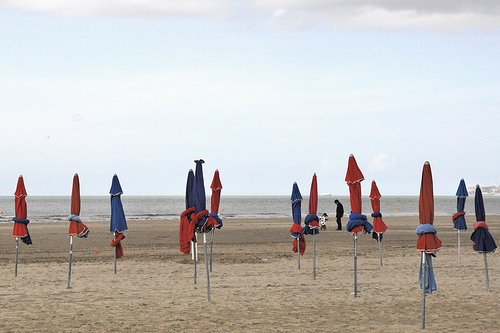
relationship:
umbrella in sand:
[11, 173, 33, 277] [3, 282, 55, 318]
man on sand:
[332, 198, 344, 232] [8, 216, 498, 331]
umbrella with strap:
[11, 172, 31, 278] [11, 215, 29, 222]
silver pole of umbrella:
[67, 232, 73, 289] [68, 172, 90, 238]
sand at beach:
[249, 296, 294, 321] [3, 217, 498, 332]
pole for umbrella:
[482, 254, 490, 290] [468, 185, 495, 290]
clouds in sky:
[1, 8, 499, 189] [6, 8, 498, 197]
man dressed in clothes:
[332, 198, 344, 232] [332, 205, 346, 226]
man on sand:
[332, 198, 344, 232] [0, 215, 499, 332]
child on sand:
[318, 211, 329, 232] [0, 215, 499, 332]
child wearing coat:
[318, 210, 328, 231] [319, 216, 327, 226]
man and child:
[332, 198, 347, 233] [318, 211, 329, 232]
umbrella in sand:
[11, 173, 33, 277] [8, 216, 498, 331]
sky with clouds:
[6, 8, 498, 197] [69, 54, 424, 126]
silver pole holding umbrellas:
[67, 232, 72, 295] [68, 173, 90, 238]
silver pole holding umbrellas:
[67, 232, 73, 289] [111, 175, 126, 259]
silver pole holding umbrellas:
[67, 232, 73, 289] [417, 162, 442, 295]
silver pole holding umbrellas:
[310, 229, 318, 279] [451, 177, 467, 229]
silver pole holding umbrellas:
[67, 232, 73, 289] [301, 173, 321, 234]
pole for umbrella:
[189, 225, 239, 320] [185, 159, 225, 303]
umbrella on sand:
[11, 173, 33, 277] [8, 216, 498, 331]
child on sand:
[318, 211, 329, 232] [246, 222, 466, 304]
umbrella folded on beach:
[11, 173, 33, 277] [11, 149, 498, 301]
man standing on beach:
[332, 198, 344, 232] [3, 217, 498, 332]